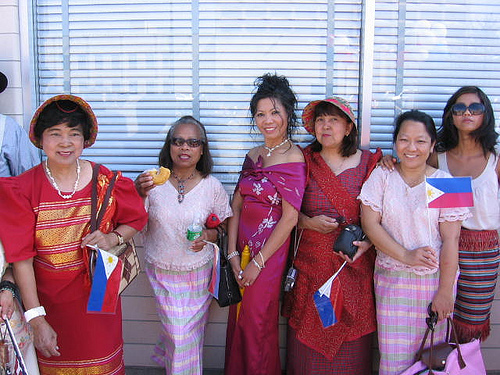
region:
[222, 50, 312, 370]
woman looks to be wearing a party dress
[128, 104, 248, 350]
woman eating a donut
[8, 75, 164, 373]
a woman wearing a red and gold dress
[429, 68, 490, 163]
a woman wearing sun glasses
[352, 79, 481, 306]
this lady waves a small flag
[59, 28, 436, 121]
the blinds behind the women give good light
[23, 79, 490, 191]
the women seem to be attending a party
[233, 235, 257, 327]
can't see what this lady is holding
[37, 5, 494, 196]
a window behind the people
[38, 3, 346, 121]
blinds in the window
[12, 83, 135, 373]
a lady in a red dress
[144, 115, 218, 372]
a lady holding food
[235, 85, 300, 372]
a lady in a pink dress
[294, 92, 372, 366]
a lady in a red hat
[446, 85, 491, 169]
a lady with sunglasses on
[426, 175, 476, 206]
a flag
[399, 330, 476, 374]
a pink purse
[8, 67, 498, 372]
women in dresses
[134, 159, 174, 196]
a woman holding a donut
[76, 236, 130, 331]
a woman holding a flag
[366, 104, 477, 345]
a woman with a flag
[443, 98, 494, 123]
a woman wearing sunglasses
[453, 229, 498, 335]
a woman wearing a striped skirt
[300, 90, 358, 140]
a woman wearing a hat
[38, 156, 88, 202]
a woman wearing a necklace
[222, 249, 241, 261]
bracelet on a woman's wrist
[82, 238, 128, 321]
Red, white and blue flag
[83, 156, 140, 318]
Lady is holding a flag and a purse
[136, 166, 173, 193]
Lady is holding food in her hand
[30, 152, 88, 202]
White beaded necklace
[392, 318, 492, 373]
Large pink bag with brown handle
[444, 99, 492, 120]
Large round dark sunglasses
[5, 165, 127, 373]
Red dress with gold stripes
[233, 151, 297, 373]
Long pink dress with with flowers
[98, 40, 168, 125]
Reflections in the window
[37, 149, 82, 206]
A white necklace.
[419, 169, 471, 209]
A flag with three colors.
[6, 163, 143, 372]
A bright red dress.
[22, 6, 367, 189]
Window with the shades down.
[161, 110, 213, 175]
A woman wearing black sunglasses.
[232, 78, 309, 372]
A woman in a pink dress with her hair up.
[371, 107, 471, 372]
A woman holding a purse and a flag.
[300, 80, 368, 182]
An older woman wearing a sun hat.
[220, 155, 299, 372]
A pink dress with a floral design.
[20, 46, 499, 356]
a group of women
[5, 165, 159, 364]
woman wearing a red dress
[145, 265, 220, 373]
a pink plaid skirt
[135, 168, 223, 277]
woman wearing a pink shirt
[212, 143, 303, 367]
woman wearing a pink dress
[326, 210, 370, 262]
woman holding a black bag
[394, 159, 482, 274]
flag on a pole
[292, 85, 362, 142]
woman wearing a hat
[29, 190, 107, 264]
gold trim on dress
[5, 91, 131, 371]
lady dressed up standing with others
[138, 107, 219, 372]
lady dressed up standing with others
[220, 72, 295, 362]
lady dressed up standing with others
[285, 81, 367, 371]
lady dressed up standing with others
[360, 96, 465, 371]
lady dressed up standing with others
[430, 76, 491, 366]
lady dressed up standing with others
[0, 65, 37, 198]
lady dressed up standing with others